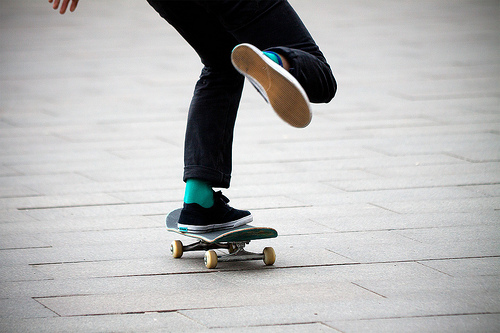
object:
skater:
[45, 1, 337, 235]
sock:
[182, 180, 218, 210]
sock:
[262, 45, 282, 66]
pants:
[147, 2, 336, 188]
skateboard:
[167, 205, 278, 270]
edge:
[164, 226, 278, 243]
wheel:
[202, 249, 218, 269]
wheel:
[264, 247, 277, 265]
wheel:
[169, 240, 184, 258]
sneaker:
[178, 189, 253, 233]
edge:
[178, 214, 255, 232]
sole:
[231, 45, 311, 128]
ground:
[3, 1, 497, 328]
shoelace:
[218, 188, 230, 204]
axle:
[218, 243, 266, 262]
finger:
[69, 0, 78, 12]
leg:
[205, 0, 337, 105]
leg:
[161, 12, 244, 193]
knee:
[325, 73, 340, 104]